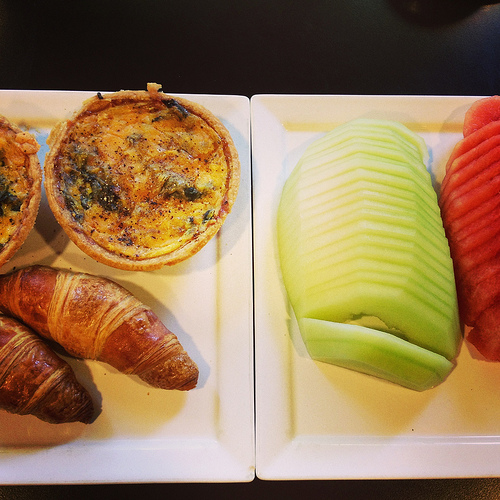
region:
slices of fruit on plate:
[302, 315, 477, 425]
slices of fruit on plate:
[320, 278, 451, 335]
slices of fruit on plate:
[308, 244, 421, 296]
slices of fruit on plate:
[306, 211, 414, 258]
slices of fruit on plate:
[306, 161, 417, 215]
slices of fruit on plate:
[308, 142, 401, 164]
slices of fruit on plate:
[326, 119, 421, 149]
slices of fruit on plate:
[468, 307, 497, 332]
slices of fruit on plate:
[449, 227, 497, 280]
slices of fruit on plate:
[450, 168, 496, 218]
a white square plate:
[0, 89, 254, 485]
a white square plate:
[250, 93, 499, 480]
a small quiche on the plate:
[44, 82, 239, 271]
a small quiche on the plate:
[0, 114, 42, 266]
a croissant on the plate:
[0, 264, 198, 391]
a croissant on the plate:
[0, 312, 94, 424]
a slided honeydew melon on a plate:
[276, 117, 461, 391]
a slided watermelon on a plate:
[437, 93, 498, 360]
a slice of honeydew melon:
[303, 339, 439, 391]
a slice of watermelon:
[462, 94, 499, 137]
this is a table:
[228, 25, 265, 56]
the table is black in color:
[332, 18, 383, 59]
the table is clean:
[340, 21, 387, 47]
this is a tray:
[231, 418, 281, 443]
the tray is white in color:
[266, 408, 315, 437]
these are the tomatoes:
[456, 140, 491, 202]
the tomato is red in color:
[469, 274, 487, 300]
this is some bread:
[18, 276, 190, 388]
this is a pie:
[50, 120, 245, 249]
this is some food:
[333, 250, 408, 327]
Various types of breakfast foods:
[0, 90, 499, 481]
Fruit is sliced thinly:
[277, 114, 499, 394]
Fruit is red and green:
[276, 100, 496, 364]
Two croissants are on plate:
[0, 265, 202, 442]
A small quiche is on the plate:
[43, 80, 239, 274]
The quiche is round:
[46, 89, 241, 278]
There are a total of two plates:
[0, 88, 498, 483]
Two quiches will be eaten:
[0, 88, 242, 272]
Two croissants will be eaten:
[1, 266, 206, 444]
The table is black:
[1, 0, 497, 96]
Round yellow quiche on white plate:
[51, 88, 241, 273]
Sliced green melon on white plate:
[275, 118, 455, 389]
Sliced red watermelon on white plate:
[437, 95, 499, 360]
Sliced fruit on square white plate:
[250, 95, 498, 480]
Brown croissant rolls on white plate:
[0, 267, 202, 422]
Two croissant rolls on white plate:
[0, 265, 199, 423]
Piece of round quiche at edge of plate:
[1, 115, 39, 262]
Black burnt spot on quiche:
[66, 168, 114, 213]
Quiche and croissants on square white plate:
[0, 88, 252, 482]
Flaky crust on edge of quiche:
[90, 80, 169, 99]